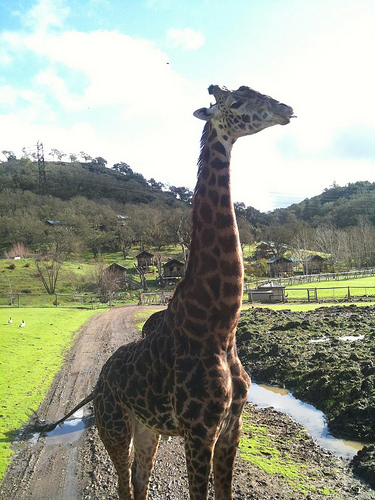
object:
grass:
[14, 325, 44, 377]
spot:
[194, 248, 219, 278]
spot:
[182, 275, 217, 307]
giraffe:
[31, 82, 297, 499]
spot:
[215, 208, 235, 230]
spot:
[222, 278, 242, 302]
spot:
[210, 155, 230, 170]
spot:
[197, 179, 207, 198]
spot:
[206, 185, 222, 208]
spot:
[199, 200, 215, 234]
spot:
[220, 231, 240, 255]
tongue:
[287, 111, 299, 120]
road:
[3, 302, 215, 496]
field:
[0, 286, 375, 499]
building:
[133, 242, 162, 278]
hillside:
[1, 182, 181, 216]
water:
[247, 378, 302, 413]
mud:
[275, 412, 303, 432]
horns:
[189, 97, 217, 126]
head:
[185, 79, 298, 140]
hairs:
[32, 422, 56, 444]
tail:
[24, 382, 96, 438]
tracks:
[56, 364, 82, 427]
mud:
[49, 467, 88, 491]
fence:
[286, 283, 364, 306]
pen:
[287, 278, 361, 295]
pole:
[35, 148, 52, 204]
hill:
[3, 155, 165, 253]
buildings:
[161, 253, 186, 282]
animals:
[11, 249, 24, 261]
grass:
[20, 257, 41, 277]